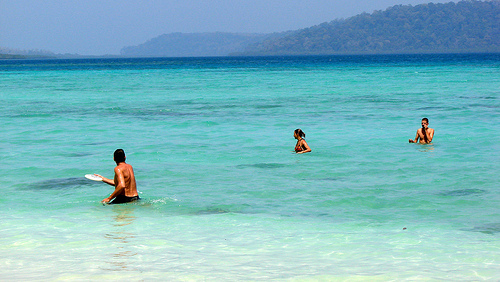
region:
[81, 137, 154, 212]
person playing in blue water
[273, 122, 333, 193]
person playing in blue water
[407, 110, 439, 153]
person playing in blue water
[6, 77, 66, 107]
person playing in blue water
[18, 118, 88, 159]
person playing in blue water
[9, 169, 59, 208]
person playing in blue water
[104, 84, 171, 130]
person playing in blue water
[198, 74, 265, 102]
person playing in blue water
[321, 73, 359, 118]
person playing in blue water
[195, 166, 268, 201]
person playing in blue water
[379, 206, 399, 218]
part of an ocean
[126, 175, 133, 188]
back of a man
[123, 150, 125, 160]
head of a man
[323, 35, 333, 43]
part of a slope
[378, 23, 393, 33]
part of a forest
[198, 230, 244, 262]
edge of a sea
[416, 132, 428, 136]
part of a chest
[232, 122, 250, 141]
part of an ocean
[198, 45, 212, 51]
part of a slope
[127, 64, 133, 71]
part of the horizon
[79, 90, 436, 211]
people in ocean water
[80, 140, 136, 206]
man holding white frisbee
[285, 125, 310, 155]
woman with bent elbow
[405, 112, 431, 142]
man with hand on side of face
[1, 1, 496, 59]
trees covering elongated land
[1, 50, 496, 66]
dark blue horizon of water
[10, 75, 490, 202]
gently rippling turquoise water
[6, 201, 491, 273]
lighter water towards shore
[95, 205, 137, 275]
man reflected on water surface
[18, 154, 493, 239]
dark shapes below ocean water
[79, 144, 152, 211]
person in the ocean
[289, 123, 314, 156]
person in the ocean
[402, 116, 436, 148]
person in the ocean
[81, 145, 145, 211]
person with no shirt on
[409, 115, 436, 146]
person with no shirt on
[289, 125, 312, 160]
woman wearing a bathing suit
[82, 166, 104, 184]
white plastic frisbee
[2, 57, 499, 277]
ocean colored light blue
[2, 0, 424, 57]
blue sky with no clouds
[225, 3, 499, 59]
hill covered with trees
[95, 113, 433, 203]
Three people in the water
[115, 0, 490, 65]
Trees in the distance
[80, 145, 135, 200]
Man getting ready to throw a frisbee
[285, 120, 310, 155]
Woman wading in the water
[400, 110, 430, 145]
Young man yelling in the water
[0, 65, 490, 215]
Turquoise water people are playing in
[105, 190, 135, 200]
Black swim trucks worn by man in the water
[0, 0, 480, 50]
Blue sky above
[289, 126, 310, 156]
Woman wearing black and red swimsuit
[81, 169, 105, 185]
White frisbee being thrown by the man